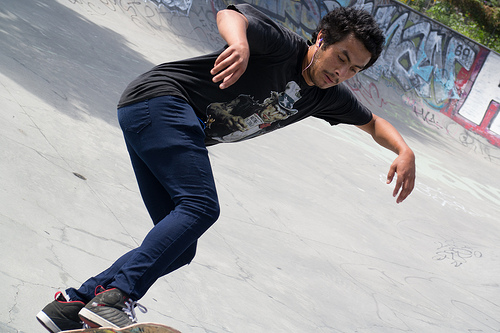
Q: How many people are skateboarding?
A: One.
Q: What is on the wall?
A: Graffiti.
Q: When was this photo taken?
A: Daytime.